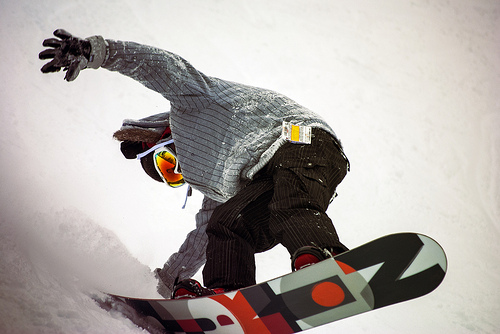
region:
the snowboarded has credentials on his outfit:
[277, 116, 317, 146]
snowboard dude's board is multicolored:
[81, 226, 453, 332]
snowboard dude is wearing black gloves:
[34, 22, 104, 84]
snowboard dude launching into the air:
[27, 20, 453, 332]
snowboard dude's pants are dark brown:
[199, 122, 347, 294]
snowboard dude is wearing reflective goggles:
[149, 140, 189, 193]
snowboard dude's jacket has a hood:
[108, 103, 178, 145]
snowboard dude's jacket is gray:
[78, 30, 346, 295]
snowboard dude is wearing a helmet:
[135, 135, 190, 194]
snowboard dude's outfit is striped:
[84, 31, 361, 298]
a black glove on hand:
[30, 17, 100, 82]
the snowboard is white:
[78, 230, 454, 331]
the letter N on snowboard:
[327, 220, 452, 313]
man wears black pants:
[22, 17, 359, 296]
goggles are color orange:
[149, 137, 189, 192]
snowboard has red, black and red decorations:
[73, 230, 450, 332]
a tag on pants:
[274, 111, 319, 148]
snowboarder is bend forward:
[30, 21, 458, 328]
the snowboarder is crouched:
[30, 16, 370, 306]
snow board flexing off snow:
[80, 227, 460, 332]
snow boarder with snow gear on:
[28, 15, 356, 293]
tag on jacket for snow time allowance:
[270, 115, 317, 156]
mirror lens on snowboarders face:
[147, 154, 185, 189]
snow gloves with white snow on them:
[38, 11, 108, 83]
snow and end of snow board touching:
[20, 231, 160, 328]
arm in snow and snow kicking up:
[117, 243, 199, 299]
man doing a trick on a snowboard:
[17, 18, 368, 333]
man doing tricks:
[18, 25, 463, 320]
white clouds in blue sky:
[404, 76, 438, 113]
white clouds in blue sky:
[285, 13, 350, 78]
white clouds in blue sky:
[304, 43, 371, 100]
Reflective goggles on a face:
[153, 143, 185, 188]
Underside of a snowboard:
[106, 230, 447, 332]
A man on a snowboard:
[36, 26, 443, 324]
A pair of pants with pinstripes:
[201, 125, 349, 295]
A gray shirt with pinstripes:
[88, 33, 339, 299]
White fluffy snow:
[2, 183, 161, 331]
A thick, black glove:
[38, 23, 90, 83]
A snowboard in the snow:
[106, 230, 448, 330]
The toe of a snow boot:
[290, 243, 322, 269]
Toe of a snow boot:
[171, 277, 202, 299]